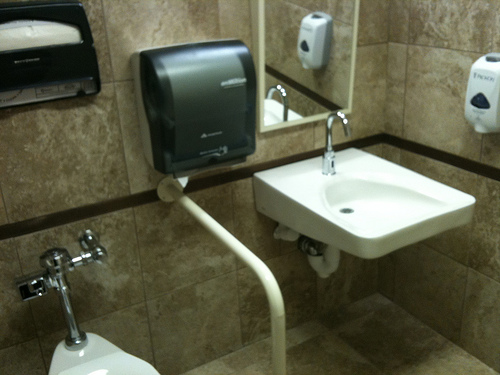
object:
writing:
[221, 77, 248, 90]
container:
[0, 0, 101, 107]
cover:
[0, 18, 84, 52]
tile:
[144, 269, 247, 375]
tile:
[0, 83, 130, 231]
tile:
[449, 279, 500, 374]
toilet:
[16, 228, 169, 374]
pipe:
[308, 244, 341, 280]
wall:
[0, 0, 497, 373]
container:
[461, 52, 500, 136]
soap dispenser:
[295, 12, 333, 71]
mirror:
[262, 1, 354, 126]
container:
[128, 39, 261, 175]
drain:
[340, 208, 354, 215]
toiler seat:
[1, 39, 94, 94]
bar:
[178, 192, 288, 373]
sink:
[252, 147, 475, 258]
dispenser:
[0, 3, 100, 109]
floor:
[167, 293, 499, 375]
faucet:
[321, 110, 351, 177]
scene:
[0, 0, 499, 375]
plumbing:
[13, 227, 110, 353]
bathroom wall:
[1, 1, 500, 373]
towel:
[158, 47, 245, 164]